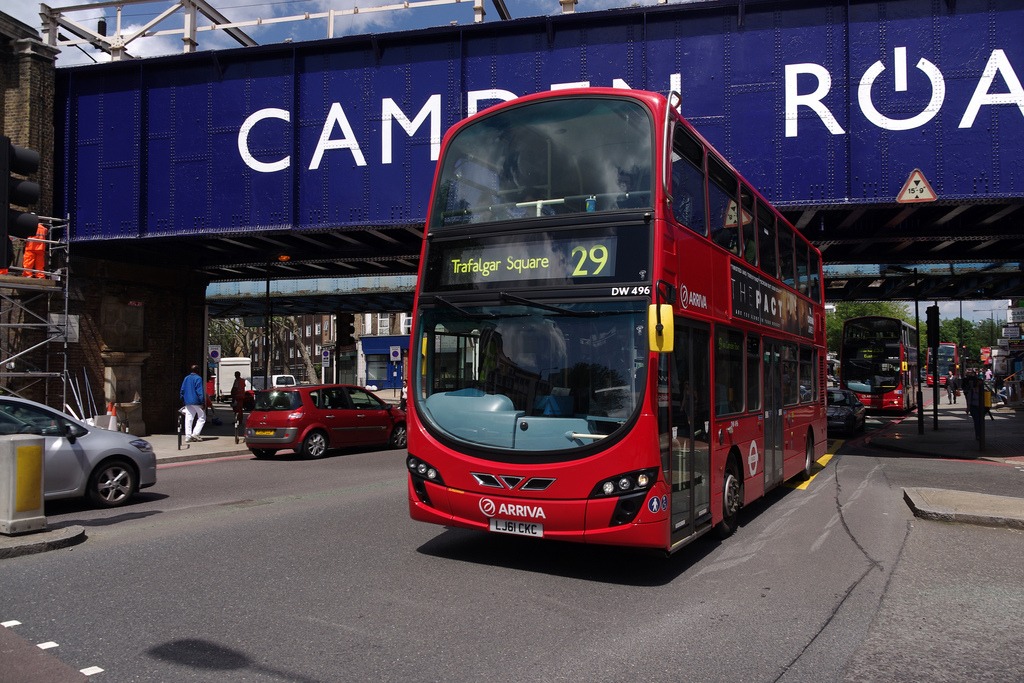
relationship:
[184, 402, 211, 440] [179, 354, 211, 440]
pants on man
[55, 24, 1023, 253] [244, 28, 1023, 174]
overpass has letters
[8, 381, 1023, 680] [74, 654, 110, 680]
road has square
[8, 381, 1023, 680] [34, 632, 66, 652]
road has square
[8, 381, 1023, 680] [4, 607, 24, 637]
road has square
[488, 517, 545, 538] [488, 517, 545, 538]
license plate has letters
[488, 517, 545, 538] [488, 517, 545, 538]
letters has numbers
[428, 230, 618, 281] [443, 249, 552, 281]
sign has letters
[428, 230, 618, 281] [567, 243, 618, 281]
sign has numbers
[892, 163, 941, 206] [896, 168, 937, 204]
sign has sign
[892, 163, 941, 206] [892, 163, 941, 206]
sign has letters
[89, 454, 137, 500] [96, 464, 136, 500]
tire has rim